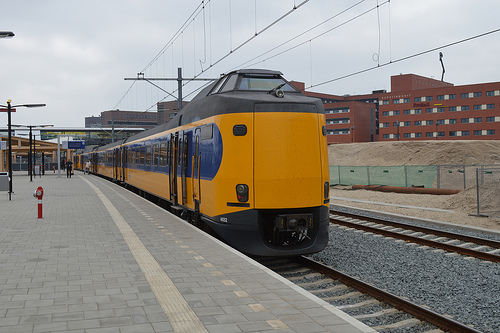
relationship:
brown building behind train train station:
[284, 44, 498, 145] [0, 25, 498, 331]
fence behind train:
[318, 154, 452, 194] [91, 79, 363, 236]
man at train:
[83, 158, 90, 172] [0, 69, 330, 255]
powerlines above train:
[99, 0, 499, 138] [71, 67, 332, 260]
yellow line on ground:
[232, 287, 249, 299] [0, 170, 355, 330]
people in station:
[63, 152, 95, 179] [11, 125, 143, 188]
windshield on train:
[239, 70, 290, 95] [71, 67, 332, 260]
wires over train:
[92, 0, 284, 118] [75, 59, 346, 266]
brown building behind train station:
[287, 72, 500, 143] [13, 108, 93, 176]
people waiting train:
[61, 159, 91, 179] [58, 61, 339, 262]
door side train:
[182, 129, 190, 213] [71, 67, 332, 260]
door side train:
[169, 130, 176, 206] [71, 67, 332, 260]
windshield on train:
[239, 77, 297, 91] [108, 57, 382, 279]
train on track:
[71, 67, 332, 260] [297, 200, 493, 329]